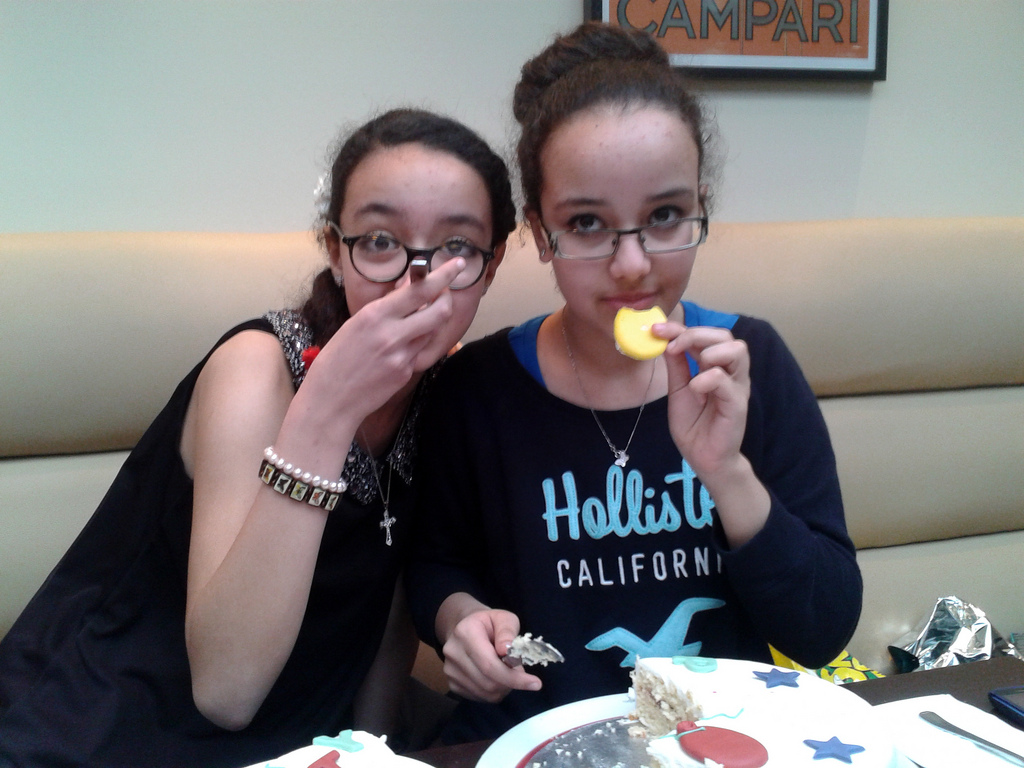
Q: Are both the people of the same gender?
A: Yes, all the people are female.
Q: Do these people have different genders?
A: No, all the people are female.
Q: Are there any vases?
A: No, there are no vases.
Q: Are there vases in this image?
A: No, there are no vases.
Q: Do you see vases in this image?
A: No, there are no vases.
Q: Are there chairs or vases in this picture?
A: No, there are no vases or chairs.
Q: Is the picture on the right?
A: Yes, the picture is on the right of the image.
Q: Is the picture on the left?
A: No, the picture is on the right of the image.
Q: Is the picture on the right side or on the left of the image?
A: The picture is on the right of the image.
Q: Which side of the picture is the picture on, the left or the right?
A: The picture is on the right of the image.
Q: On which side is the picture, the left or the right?
A: The picture is on the right of the image.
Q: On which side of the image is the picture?
A: The picture is on the right of the image.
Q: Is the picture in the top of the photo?
A: Yes, the picture is in the top of the image.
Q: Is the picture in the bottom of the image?
A: No, the picture is in the top of the image.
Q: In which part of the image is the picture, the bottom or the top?
A: The picture is in the top of the image.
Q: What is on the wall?
A: The picture is on the wall.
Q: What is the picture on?
A: The picture is on the wall.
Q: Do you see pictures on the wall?
A: Yes, there is a picture on the wall.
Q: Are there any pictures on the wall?
A: Yes, there is a picture on the wall.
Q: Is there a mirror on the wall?
A: No, there is a picture on the wall.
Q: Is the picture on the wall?
A: Yes, the picture is on the wall.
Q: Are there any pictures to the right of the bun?
A: Yes, there is a picture to the right of the bun.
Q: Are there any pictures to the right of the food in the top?
A: Yes, there is a picture to the right of the bun.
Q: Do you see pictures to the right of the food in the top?
A: Yes, there is a picture to the right of the bun.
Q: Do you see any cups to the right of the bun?
A: No, there is a picture to the right of the bun.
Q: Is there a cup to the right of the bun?
A: No, there is a picture to the right of the bun.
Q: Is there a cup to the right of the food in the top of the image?
A: No, there is a picture to the right of the bun.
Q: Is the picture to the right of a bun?
A: Yes, the picture is to the right of a bun.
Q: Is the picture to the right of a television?
A: No, the picture is to the right of a bun.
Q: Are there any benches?
A: Yes, there is a bench.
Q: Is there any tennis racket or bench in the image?
A: Yes, there is a bench.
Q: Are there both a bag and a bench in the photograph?
A: No, there is a bench but no bags.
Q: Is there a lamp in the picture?
A: No, there are no lamps.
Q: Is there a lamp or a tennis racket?
A: No, there are no lamps or rackets.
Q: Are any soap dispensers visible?
A: No, there are no soap dispensers.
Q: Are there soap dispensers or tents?
A: No, there are no soap dispensers or tents.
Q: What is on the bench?
A: The paper is on the bench.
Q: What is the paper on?
A: The paper is on the bench.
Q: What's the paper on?
A: The paper is on the bench.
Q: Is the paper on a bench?
A: Yes, the paper is on a bench.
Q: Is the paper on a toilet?
A: No, the paper is on a bench.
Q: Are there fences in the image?
A: No, there are no fences.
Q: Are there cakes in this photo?
A: Yes, there is a cake.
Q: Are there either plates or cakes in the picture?
A: Yes, there is a cake.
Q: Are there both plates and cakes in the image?
A: Yes, there are both a cake and a plate.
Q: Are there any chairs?
A: No, there are no chairs.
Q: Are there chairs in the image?
A: No, there are no chairs.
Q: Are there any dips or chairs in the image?
A: No, there are no chairs or dips.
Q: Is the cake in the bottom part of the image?
A: Yes, the cake is in the bottom of the image.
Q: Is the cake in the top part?
A: No, the cake is in the bottom of the image.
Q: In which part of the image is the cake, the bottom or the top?
A: The cake is in the bottom of the image.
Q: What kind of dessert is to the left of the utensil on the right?
A: The dessert is a cake.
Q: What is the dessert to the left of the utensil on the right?
A: The dessert is a cake.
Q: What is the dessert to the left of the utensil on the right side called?
A: The dessert is a cake.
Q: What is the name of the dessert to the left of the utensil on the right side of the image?
A: The dessert is a cake.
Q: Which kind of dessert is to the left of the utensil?
A: The dessert is a cake.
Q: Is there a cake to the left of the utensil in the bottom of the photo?
A: Yes, there is a cake to the left of the utensil.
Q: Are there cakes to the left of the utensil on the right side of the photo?
A: Yes, there is a cake to the left of the utensil.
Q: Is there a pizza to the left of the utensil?
A: No, there is a cake to the left of the utensil.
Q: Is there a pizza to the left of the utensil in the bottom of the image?
A: No, there is a cake to the left of the utensil.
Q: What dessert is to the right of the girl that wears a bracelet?
A: The dessert is a cake.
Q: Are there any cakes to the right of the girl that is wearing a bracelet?
A: Yes, there is a cake to the right of the girl.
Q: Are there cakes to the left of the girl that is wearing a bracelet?
A: No, the cake is to the right of the girl.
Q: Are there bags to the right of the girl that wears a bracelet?
A: No, there is a cake to the right of the girl.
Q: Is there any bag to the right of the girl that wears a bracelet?
A: No, there is a cake to the right of the girl.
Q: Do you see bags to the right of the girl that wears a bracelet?
A: No, there is a cake to the right of the girl.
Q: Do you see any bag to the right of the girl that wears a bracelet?
A: No, there is a cake to the right of the girl.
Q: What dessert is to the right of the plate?
A: The dessert is a cake.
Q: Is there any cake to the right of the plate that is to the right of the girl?
A: Yes, there is a cake to the right of the plate.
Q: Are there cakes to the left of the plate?
A: No, the cake is to the right of the plate.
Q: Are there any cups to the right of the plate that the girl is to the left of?
A: No, there is a cake to the right of the plate.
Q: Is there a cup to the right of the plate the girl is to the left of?
A: No, there is a cake to the right of the plate.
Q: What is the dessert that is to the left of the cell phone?
A: The dessert is a cake.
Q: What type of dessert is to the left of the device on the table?
A: The dessert is a cake.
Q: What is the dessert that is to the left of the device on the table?
A: The dessert is a cake.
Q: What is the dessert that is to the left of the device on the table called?
A: The dessert is a cake.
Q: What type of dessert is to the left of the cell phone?
A: The dessert is a cake.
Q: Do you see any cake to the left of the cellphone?
A: Yes, there is a cake to the left of the cellphone.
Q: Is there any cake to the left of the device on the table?
A: Yes, there is a cake to the left of the cellphone.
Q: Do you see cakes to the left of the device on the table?
A: Yes, there is a cake to the left of the cellphone.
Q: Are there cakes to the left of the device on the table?
A: Yes, there is a cake to the left of the cellphone.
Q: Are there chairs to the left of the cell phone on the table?
A: No, there is a cake to the left of the cell phone.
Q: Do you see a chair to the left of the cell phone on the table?
A: No, there is a cake to the left of the cell phone.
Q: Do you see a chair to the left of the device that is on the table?
A: No, there is a cake to the left of the cell phone.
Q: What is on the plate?
A: The cake is on the plate.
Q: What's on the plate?
A: The cake is on the plate.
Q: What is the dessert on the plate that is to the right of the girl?
A: The dessert is a cake.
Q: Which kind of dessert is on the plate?
A: The dessert is a cake.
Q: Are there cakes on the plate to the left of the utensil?
A: Yes, there is a cake on the plate.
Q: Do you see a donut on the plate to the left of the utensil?
A: No, there is a cake on the plate.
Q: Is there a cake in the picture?
A: Yes, there is a cake.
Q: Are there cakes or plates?
A: Yes, there is a cake.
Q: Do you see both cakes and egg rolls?
A: No, there is a cake but no egg rolls.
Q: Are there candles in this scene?
A: No, there are no candles.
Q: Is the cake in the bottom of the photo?
A: Yes, the cake is in the bottom of the image.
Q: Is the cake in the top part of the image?
A: No, the cake is in the bottom of the image.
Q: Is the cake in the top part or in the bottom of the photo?
A: The cake is in the bottom of the image.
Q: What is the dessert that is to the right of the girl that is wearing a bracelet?
A: The dessert is a cake.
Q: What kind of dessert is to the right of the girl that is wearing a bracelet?
A: The dessert is a cake.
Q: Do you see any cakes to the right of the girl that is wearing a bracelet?
A: Yes, there is a cake to the right of the girl.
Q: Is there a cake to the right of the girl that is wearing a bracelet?
A: Yes, there is a cake to the right of the girl.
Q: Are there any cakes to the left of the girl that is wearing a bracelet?
A: No, the cake is to the right of the girl.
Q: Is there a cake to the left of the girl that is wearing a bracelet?
A: No, the cake is to the right of the girl.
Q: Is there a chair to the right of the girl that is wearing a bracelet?
A: No, there is a cake to the right of the girl.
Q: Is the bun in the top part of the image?
A: Yes, the bun is in the top of the image.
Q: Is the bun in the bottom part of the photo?
A: No, the bun is in the top of the image.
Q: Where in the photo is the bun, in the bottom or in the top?
A: The bun is in the top of the image.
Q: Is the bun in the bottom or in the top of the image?
A: The bun is in the top of the image.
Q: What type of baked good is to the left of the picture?
A: The food is a bun.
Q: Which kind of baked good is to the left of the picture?
A: The food is a bun.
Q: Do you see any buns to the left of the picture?
A: Yes, there is a bun to the left of the picture.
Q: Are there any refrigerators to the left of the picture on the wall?
A: No, there is a bun to the left of the picture.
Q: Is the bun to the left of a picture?
A: Yes, the bun is to the left of a picture.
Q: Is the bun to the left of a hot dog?
A: No, the bun is to the left of a picture.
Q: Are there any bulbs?
A: No, there are no bulbs.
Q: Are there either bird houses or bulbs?
A: No, there are no bulbs or bird houses.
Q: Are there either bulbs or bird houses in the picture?
A: No, there are no bulbs or bird houses.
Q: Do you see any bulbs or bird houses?
A: No, there are no bulbs or bird houses.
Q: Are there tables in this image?
A: Yes, there is a table.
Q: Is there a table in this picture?
A: Yes, there is a table.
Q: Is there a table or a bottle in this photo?
A: Yes, there is a table.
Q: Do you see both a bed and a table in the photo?
A: No, there is a table but no beds.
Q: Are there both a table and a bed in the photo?
A: No, there is a table but no beds.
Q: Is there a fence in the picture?
A: No, there are no fences.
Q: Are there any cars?
A: No, there are no cars.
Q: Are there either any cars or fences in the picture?
A: No, there are no cars or fences.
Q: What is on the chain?
A: The cross is on the chain.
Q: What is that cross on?
A: The cross is on the chain.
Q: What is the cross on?
A: The cross is on the chain.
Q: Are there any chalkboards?
A: No, there are no chalkboards.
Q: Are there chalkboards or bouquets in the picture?
A: No, there are no chalkboards or bouquets.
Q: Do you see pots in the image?
A: No, there are no pots.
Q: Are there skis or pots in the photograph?
A: No, there are no pots or skis.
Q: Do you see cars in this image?
A: No, there are no cars.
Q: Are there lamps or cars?
A: No, there are no cars or lamps.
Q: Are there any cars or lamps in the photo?
A: No, there are no cars or lamps.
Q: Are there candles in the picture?
A: No, there are no candles.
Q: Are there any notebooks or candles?
A: No, there are no candles or notebooks.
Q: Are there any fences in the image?
A: No, there are no fences.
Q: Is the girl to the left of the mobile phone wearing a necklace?
A: Yes, the girl is wearing a necklace.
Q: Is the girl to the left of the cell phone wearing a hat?
A: No, the girl is wearing a necklace.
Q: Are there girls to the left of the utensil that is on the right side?
A: Yes, there is a girl to the left of the utensil.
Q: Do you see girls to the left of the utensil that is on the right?
A: Yes, there is a girl to the left of the utensil.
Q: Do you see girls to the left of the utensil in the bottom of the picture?
A: Yes, there is a girl to the left of the utensil.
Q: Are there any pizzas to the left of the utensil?
A: No, there is a girl to the left of the utensil.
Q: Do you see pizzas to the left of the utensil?
A: No, there is a girl to the left of the utensil.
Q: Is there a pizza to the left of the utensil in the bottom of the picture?
A: No, there is a girl to the left of the utensil.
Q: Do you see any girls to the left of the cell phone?
A: Yes, there is a girl to the left of the cell phone.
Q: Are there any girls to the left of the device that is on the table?
A: Yes, there is a girl to the left of the cell phone.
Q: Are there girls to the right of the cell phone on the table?
A: No, the girl is to the left of the mobile phone.